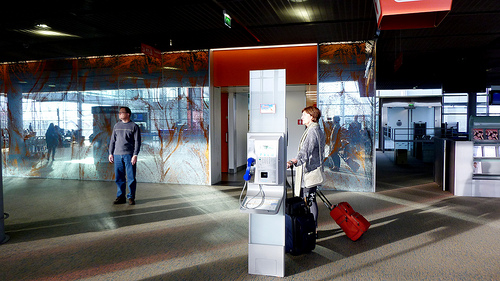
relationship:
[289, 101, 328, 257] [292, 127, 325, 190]
woman has handbag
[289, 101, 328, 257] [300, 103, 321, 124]
woman has hair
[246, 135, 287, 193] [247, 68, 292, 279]
telephone on wall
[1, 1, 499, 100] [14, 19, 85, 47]
ceiling has light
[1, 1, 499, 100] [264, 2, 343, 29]
ceiling has light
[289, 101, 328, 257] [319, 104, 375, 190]
person in reflection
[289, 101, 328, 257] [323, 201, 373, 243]
woman has luggage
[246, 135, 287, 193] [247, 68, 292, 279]
telephone on a stand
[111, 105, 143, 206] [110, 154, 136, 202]
man has jeans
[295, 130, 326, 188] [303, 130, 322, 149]
handbag on shoulder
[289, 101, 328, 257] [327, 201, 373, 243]
woman has a suitcase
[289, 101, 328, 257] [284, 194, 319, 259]
woman has a suitcase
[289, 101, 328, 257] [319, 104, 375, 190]
woman has reflection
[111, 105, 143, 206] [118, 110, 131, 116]
man has glasses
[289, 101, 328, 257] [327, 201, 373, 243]
woman has suitcase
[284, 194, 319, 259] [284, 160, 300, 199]
suitcase has handle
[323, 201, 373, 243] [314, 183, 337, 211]
luggage has a handle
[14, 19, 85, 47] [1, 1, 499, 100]
light on ceiling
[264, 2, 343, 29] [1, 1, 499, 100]
light on ceiling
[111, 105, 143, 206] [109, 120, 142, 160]
man has shirt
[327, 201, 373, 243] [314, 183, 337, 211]
luggage has a handle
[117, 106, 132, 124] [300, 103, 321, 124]
hair has hair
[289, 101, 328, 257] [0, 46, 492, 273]
woman in lobby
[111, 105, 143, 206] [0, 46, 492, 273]
man in lobby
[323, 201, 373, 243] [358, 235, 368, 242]
luggage has wheels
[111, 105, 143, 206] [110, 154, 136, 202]
man in jeans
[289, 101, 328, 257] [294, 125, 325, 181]
woman in a sweater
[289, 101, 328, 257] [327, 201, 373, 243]
woman has luggage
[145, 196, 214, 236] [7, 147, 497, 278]
shadow on floor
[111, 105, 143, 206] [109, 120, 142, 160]
man in sweater